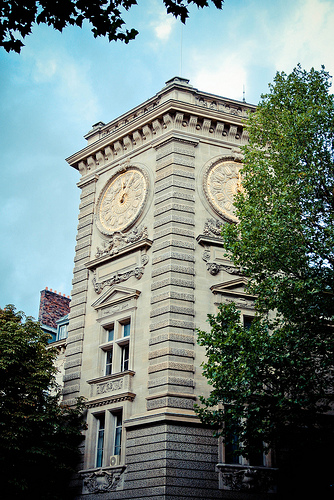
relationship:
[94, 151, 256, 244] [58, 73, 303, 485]
clock in tower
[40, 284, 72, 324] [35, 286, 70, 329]
chimney on chimney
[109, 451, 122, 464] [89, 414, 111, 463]
fan in window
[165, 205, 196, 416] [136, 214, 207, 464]
ribbed corner of structure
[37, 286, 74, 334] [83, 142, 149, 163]
square flat chimney on roof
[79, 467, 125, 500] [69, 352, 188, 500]
design element on building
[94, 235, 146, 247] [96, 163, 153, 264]
decorative element under clock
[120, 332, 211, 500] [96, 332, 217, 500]
part of a building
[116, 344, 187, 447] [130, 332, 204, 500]
side of a building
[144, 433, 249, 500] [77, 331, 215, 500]
edge of a wall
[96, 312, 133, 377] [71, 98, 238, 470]
windows in building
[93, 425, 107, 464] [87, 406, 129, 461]
curtains at windows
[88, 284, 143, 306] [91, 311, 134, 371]
triangle above window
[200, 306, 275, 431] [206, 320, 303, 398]
leaves in a branch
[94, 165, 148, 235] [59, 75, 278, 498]
clock on building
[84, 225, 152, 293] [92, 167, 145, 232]
decorative area below clock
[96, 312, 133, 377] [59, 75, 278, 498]
windows on building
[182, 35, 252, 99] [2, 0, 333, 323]
clouds in sky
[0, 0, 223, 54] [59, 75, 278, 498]
tree's leaves hang over building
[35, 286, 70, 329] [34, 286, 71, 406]
chimney behind building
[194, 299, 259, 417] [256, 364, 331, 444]
leaves in branch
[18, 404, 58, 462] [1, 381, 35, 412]
leaves in branch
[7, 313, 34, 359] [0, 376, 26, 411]
leaves in branch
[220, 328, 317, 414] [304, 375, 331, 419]
leaves in branch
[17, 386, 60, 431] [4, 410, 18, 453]
leaves in branch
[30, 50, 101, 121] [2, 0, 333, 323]
clouds in sky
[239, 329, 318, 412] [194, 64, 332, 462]
leaves on tree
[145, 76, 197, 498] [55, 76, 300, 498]
corner of clock tower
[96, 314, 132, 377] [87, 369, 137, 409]
windows with balcony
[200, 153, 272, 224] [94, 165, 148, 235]
clock face of clock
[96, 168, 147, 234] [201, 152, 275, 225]
clock face of clock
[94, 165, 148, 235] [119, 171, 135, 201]
clock with hands